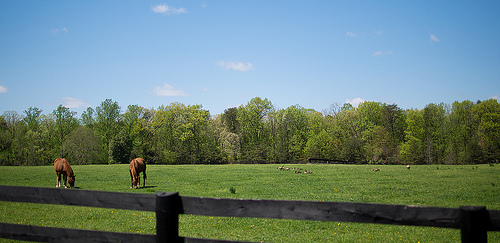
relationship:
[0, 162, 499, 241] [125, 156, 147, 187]
pasture has horse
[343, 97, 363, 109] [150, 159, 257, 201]
cloud on grass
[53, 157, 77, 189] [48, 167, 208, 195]
animal on ground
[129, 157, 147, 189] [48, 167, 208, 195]
animal on ground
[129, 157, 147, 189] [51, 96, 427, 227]
animal graze in field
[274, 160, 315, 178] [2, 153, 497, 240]
animals grouped in pasture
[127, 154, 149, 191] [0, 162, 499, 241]
animal in pasture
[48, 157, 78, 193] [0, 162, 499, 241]
animal in pasture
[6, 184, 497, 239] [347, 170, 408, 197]
fence by grass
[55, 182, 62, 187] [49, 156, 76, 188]
feet on horse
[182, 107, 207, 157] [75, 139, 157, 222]
tree behind horse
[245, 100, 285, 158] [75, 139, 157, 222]
tree behind horse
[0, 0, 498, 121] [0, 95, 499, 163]
blue sky above trees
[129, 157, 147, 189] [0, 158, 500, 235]
animal in field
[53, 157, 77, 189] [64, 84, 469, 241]
animal in field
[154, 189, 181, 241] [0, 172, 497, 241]
fence post on fence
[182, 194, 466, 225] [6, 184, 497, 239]
slat on fence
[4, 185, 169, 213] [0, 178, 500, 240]
slat on fence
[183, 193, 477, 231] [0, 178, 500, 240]
slat on fence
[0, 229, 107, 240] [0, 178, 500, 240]
slat on fence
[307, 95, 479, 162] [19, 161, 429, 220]
trees behind field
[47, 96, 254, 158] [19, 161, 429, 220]
trees behind field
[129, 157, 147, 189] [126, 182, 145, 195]
animal eating grass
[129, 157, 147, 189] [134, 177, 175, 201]
animal eating grass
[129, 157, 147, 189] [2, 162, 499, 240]
animal in field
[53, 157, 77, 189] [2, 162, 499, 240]
animal in field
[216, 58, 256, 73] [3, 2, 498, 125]
cloud in sky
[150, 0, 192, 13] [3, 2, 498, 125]
cloud in sky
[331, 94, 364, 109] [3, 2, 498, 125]
cloud in sky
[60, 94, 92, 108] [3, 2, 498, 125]
cloud in sky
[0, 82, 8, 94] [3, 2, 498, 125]
cloud in sky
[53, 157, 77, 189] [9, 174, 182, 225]
animal in field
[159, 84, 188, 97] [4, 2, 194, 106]
white cloud in blue sky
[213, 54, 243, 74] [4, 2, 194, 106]
white cloud in blue sky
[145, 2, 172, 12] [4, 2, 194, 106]
white cloud in blue sky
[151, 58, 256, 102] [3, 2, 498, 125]
clouds in sky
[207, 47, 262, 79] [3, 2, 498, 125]
cloud in sky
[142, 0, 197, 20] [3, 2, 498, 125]
cloud in sky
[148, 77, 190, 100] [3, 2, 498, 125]
cloud in sky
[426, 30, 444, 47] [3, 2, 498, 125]
cloud in sky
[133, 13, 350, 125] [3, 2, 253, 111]
clouds in blue sky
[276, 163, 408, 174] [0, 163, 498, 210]
several geese grazing in field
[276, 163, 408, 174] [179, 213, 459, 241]
several geese grazing in field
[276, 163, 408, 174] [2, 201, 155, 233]
several geese grazing in field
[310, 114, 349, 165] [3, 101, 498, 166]
green tree in forest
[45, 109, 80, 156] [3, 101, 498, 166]
green tree in forest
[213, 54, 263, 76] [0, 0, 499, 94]
clouds in sky